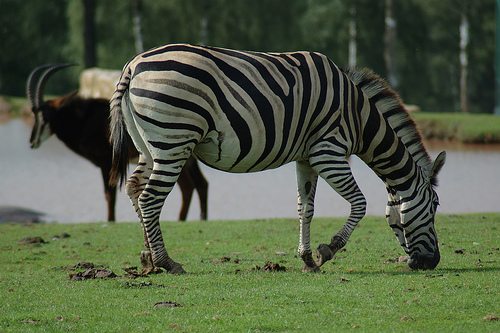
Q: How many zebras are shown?
A: 1.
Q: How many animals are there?
A: 2.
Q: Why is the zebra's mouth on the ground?
A: Grazing.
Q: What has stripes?
A: Zebra.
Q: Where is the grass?
A: Ground.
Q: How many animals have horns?
A: 1.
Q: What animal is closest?
A: Zebra.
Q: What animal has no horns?
A: Zebra.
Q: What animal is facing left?
A: Horned animal.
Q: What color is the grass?
A: Green.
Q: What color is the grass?
A: Green.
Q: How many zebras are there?
A: One.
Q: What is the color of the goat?
A: Black.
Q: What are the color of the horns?
A: Black.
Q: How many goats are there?
A: One.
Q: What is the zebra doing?
A: Standing.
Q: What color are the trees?
A: Green.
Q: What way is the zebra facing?
A: Right.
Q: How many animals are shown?
A: Two.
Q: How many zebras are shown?
A: One.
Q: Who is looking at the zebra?
A: Photographer.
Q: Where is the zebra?
A: Next to the lake.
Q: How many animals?
A: 2.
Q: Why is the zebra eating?
A: Hungry.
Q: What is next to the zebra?
A: Another animal.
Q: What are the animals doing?
A: Eating.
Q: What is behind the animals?
A: Trees.